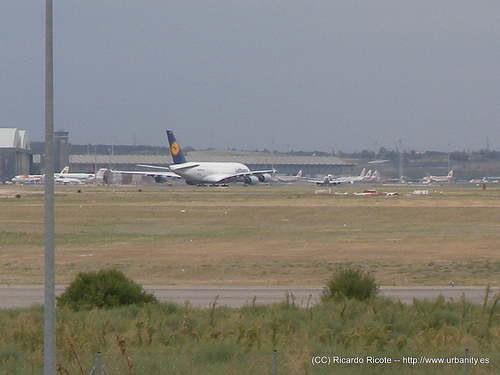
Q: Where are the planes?
A: At an airstrip.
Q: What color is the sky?
A: A bluish grey.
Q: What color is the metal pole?
A: Grey.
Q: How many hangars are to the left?
A: Two.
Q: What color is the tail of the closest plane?
A: Blue and yellow.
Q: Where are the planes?
A: On the runway.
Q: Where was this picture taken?
A: At an airport.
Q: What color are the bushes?
A: Green.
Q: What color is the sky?
A: Gray.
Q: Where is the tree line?
A: Behind the airport.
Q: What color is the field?
A: Brown.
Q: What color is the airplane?
A: White.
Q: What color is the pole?
A: Gray.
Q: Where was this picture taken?
A: An airfield.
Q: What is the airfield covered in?
A: Grass.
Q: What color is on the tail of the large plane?
A: Blue and yellow.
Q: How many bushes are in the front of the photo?
A: 2.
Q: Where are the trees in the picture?
A: In the distance.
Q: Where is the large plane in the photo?
A: In the middle.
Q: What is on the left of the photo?
A: A pole.